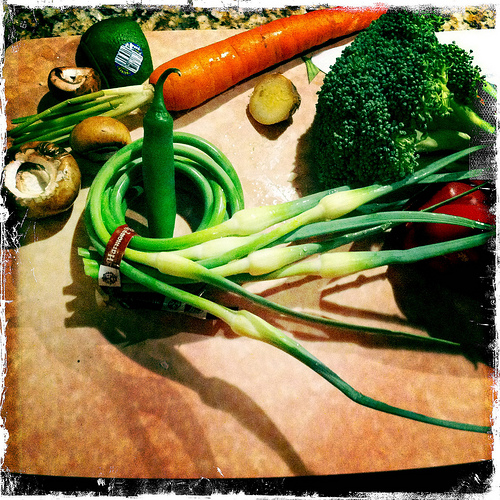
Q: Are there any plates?
A: No, there are no plates.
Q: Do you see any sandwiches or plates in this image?
A: No, there are no plates or sandwiches.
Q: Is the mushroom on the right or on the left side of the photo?
A: The mushroom is on the left of the image.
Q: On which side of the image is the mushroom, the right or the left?
A: The mushroom is on the left of the image.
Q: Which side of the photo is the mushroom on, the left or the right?
A: The mushroom is on the left of the image.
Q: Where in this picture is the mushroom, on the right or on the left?
A: The mushroom is on the left of the image.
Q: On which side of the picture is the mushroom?
A: The mushroom is on the left of the image.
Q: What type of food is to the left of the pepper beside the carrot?
A: The food is a mushroom.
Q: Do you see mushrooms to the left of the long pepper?
A: Yes, there is a mushroom to the left of the pepper.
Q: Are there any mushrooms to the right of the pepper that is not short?
A: No, the mushroom is to the left of the pepper.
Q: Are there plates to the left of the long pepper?
A: No, there is a mushroom to the left of the pepper.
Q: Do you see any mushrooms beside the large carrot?
A: Yes, there is a mushroom beside the carrot.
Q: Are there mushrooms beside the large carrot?
A: Yes, there is a mushroom beside the carrot.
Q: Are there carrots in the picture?
A: Yes, there is a carrot.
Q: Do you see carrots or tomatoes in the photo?
A: Yes, there is a carrot.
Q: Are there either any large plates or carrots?
A: Yes, there is a large carrot.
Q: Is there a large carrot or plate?
A: Yes, there is a large carrot.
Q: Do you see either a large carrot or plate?
A: Yes, there is a large carrot.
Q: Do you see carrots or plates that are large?
A: Yes, the carrot is large.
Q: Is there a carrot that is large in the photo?
A: Yes, there is a large carrot.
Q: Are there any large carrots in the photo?
A: Yes, there is a large carrot.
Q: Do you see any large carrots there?
A: Yes, there is a large carrot.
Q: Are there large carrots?
A: Yes, there is a large carrot.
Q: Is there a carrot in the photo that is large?
A: Yes, there is a carrot that is large.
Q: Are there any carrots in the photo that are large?
A: Yes, there is a carrot that is large.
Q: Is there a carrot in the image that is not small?
A: Yes, there is a large carrot.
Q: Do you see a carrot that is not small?
A: Yes, there is a large carrot.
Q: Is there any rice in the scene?
A: No, there is no rice.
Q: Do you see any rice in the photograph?
A: No, there is no rice.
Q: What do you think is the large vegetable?
A: The vegetable is a carrot.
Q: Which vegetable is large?
A: The vegetable is a carrot.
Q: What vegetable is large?
A: The vegetable is a carrot.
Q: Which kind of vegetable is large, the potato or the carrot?
A: The carrot is large.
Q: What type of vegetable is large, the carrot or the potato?
A: The carrot is large.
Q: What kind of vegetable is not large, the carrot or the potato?
A: The potato is not large.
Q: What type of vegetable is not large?
A: The vegetable is a potato.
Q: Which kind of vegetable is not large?
A: The vegetable is a potato.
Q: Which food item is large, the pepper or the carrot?
A: The carrot is large.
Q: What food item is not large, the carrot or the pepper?
A: The pepper is not large.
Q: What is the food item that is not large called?
A: The food item is a pepper.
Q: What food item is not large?
A: The food item is a pepper.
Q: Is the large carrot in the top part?
A: Yes, the carrot is in the top of the image.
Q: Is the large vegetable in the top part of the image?
A: Yes, the carrot is in the top of the image.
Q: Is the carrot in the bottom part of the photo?
A: No, the carrot is in the top of the image.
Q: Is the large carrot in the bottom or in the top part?
A: The carrot is in the top of the image.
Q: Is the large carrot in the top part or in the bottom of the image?
A: The carrot is in the top of the image.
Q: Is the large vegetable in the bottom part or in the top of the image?
A: The carrot is in the top of the image.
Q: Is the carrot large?
A: Yes, the carrot is large.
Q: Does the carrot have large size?
A: Yes, the carrot is large.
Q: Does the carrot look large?
A: Yes, the carrot is large.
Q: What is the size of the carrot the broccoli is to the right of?
A: The carrot is large.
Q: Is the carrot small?
A: No, the carrot is large.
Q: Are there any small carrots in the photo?
A: No, there is a carrot but it is large.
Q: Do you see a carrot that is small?
A: No, there is a carrot but it is large.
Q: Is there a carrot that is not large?
A: No, there is a carrot but it is large.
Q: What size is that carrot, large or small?
A: The carrot is large.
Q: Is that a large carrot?
A: Yes, that is a large carrot.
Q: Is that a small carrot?
A: No, that is a large carrot.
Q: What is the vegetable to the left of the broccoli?
A: The vegetable is a carrot.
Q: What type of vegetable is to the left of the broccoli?
A: The vegetable is a carrot.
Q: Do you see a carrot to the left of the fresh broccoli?
A: Yes, there is a carrot to the left of the broccoli.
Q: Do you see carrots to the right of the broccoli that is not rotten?
A: No, the carrot is to the left of the broccoli.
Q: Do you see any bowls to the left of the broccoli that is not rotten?
A: No, there is a carrot to the left of the broccoli.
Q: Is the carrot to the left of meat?
A: No, the carrot is to the left of the broccoli.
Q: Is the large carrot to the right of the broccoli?
A: No, the carrot is to the left of the broccoli.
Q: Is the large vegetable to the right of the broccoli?
A: No, the carrot is to the left of the broccoli.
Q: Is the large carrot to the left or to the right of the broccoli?
A: The carrot is to the left of the broccoli.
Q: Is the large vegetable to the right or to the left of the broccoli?
A: The carrot is to the left of the broccoli.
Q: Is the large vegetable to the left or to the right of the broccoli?
A: The carrot is to the left of the broccoli.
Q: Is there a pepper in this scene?
A: Yes, there is a pepper.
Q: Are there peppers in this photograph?
A: Yes, there is a pepper.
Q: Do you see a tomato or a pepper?
A: Yes, there is a pepper.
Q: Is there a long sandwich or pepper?
A: Yes, there is a long pepper.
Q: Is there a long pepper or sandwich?
A: Yes, there is a long pepper.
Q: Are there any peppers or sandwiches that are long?
A: Yes, the pepper is long.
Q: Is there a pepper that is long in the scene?
A: Yes, there is a long pepper.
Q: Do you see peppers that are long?
A: Yes, there is a pepper that is long.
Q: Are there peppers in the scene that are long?
A: Yes, there is a pepper that is long.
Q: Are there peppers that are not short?
A: Yes, there is a long pepper.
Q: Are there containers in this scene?
A: No, there are no containers.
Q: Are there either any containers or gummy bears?
A: No, there are no containers or gummy bears.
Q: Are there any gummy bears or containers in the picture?
A: No, there are no containers or gummy bears.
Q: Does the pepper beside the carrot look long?
A: Yes, the pepper is long.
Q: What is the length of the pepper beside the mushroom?
A: The pepper is long.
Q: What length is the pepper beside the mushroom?
A: The pepper is long.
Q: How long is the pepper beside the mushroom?
A: The pepper is long.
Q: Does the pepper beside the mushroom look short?
A: No, the pepper is long.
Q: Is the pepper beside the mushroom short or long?
A: The pepper is long.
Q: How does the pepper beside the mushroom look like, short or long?
A: The pepper is long.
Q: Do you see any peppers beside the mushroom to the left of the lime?
A: Yes, there is a pepper beside the mushroom.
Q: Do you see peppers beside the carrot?
A: Yes, there is a pepper beside the carrot.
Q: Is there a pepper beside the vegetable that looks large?
A: Yes, there is a pepper beside the carrot.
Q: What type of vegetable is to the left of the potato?
A: The vegetable is a pepper.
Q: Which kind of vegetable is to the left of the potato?
A: The vegetable is a pepper.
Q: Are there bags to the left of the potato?
A: No, there is a pepper to the left of the potato.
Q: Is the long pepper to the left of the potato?
A: Yes, the pepper is to the left of the potato.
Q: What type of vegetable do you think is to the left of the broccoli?
A: The vegetable is a pepper.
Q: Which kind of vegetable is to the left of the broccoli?
A: The vegetable is a pepper.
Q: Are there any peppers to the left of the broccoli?
A: Yes, there is a pepper to the left of the broccoli.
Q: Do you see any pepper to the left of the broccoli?
A: Yes, there is a pepper to the left of the broccoli.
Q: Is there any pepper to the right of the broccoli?
A: No, the pepper is to the left of the broccoli.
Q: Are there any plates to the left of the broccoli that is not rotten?
A: No, there is a pepper to the left of the broccoli.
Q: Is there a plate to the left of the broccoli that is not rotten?
A: No, there is a pepper to the left of the broccoli.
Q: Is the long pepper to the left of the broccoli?
A: Yes, the pepper is to the left of the broccoli.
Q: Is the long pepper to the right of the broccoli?
A: No, the pepper is to the left of the broccoli.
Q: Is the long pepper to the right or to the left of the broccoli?
A: The pepper is to the left of the broccoli.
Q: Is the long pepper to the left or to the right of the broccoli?
A: The pepper is to the left of the broccoli.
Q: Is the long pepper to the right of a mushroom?
A: Yes, the pepper is to the right of a mushroom.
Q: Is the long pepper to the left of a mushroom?
A: No, the pepper is to the right of a mushroom.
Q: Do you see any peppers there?
A: Yes, there is a pepper.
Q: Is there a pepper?
A: Yes, there is a pepper.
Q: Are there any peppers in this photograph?
A: Yes, there is a pepper.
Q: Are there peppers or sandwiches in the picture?
A: Yes, there is a pepper.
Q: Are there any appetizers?
A: No, there are no appetizers.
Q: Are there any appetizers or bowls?
A: No, there are no appetizers or bowls.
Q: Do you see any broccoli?
A: Yes, there is broccoli.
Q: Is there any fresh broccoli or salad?
A: Yes, there is fresh broccoli.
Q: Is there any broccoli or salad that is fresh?
A: Yes, the broccoli is fresh.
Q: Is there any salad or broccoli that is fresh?
A: Yes, the broccoli is fresh.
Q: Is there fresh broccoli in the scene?
A: Yes, there is fresh broccoli.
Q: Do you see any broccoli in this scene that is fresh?
A: Yes, there is broccoli that is fresh.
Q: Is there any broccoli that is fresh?
A: Yes, there is broccoli that is fresh.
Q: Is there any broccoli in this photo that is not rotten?
A: Yes, there is fresh broccoli.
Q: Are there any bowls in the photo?
A: No, there are no bowls.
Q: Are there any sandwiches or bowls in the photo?
A: No, there are no bowls or sandwiches.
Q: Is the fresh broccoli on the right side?
A: Yes, the broccoli is on the right of the image.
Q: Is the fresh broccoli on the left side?
A: No, the broccoli is on the right of the image.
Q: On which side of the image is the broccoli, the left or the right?
A: The broccoli is on the right of the image.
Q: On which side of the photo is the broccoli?
A: The broccoli is on the right of the image.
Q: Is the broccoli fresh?
A: Yes, the broccoli is fresh.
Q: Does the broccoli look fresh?
A: Yes, the broccoli is fresh.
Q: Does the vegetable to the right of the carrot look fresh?
A: Yes, the broccoli is fresh.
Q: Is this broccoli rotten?
A: No, the broccoli is fresh.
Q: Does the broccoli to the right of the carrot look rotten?
A: No, the broccoli is fresh.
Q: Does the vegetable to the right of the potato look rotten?
A: No, the broccoli is fresh.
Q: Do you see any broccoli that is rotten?
A: No, there is broccoli but it is fresh.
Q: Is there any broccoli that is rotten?
A: No, there is broccoli but it is fresh.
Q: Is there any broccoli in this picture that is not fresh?
A: No, there is broccoli but it is fresh.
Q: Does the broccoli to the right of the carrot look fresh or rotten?
A: The broccoli is fresh.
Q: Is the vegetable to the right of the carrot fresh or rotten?
A: The broccoli is fresh.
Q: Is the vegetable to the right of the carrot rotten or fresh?
A: The broccoli is fresh.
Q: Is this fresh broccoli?
A: Yes, this is fresh broccoli.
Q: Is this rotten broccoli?
A: No, this is fresh broccoli.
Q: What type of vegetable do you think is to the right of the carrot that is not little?
A: The vegetable is broccoli.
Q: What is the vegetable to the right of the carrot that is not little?
A: The vegetable is broccoli.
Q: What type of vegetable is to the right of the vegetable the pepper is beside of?
A: The vegetable is broccoli.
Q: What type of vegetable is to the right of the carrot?
A: The vegetable is broccoli.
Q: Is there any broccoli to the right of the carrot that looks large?
A: Yes, there is broccoli to the right of the carrot.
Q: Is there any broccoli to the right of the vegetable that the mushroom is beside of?
A: Yes, there is broccoli to the right of the carrot.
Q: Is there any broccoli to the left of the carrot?
A: No, the broccoli is to the right of the carrot.